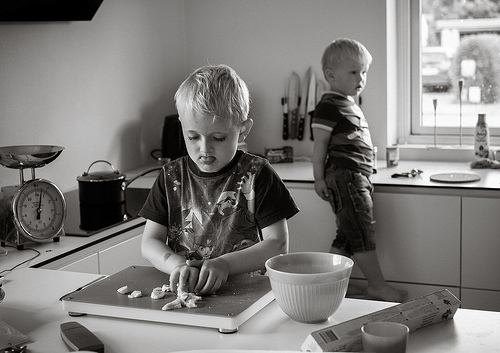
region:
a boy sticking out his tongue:
[196, 152, 221, 164]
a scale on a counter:
[1, 143, 67, 250]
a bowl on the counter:
[266, 256, 354, 322]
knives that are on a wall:
[271, 63, 335, 146]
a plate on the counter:
[424, 169, 489, 188]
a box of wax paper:
[301, 287, 474, 349]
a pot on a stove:
[75, 158, 159, 210]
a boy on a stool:
[306, 27, 414, 303]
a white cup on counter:
[356, 318, 416, 351]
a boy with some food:
[117, 234, 254, 324]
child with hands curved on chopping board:
[57, 65, 287, 330]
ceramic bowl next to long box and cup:
[266, 250, 456, 350]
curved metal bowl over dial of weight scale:
[0, 140, 65, 246]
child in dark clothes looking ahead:
[310, 32, 371, 247]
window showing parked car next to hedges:
[385, 1, 495, 146]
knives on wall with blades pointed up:
[280, 55, 317, 145]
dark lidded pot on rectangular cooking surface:
[56, 155, 153, 236]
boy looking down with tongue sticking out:
[171, 60, 251, 175]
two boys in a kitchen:
[136, 35, 377, 296]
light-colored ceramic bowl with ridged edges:
[265, 251, 355, 323]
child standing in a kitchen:
[120, 59, 302, 297]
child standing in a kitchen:
[310, 34, 408, 301]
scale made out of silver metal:
[0, 134, 76, 254]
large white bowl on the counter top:
[262, 247, 357, 329]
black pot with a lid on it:
[69, 153, 171, 210]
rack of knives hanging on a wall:
[272, 63, 327, 152]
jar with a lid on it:
[465, 111, 495, 166]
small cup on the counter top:
[355, 314, 416, 352]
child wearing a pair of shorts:
[302, 37, 414, 304]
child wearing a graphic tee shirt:
[127, 64, 294, 306]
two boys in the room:
[108, 38, 394, 247]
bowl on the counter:
[266, 250, 358, 322]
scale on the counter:
[5, 133, 76, 245]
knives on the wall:
[263, 60, 323, 147]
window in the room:
[413, 22, 496, 137]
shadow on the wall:
[99, 81, 165, 168]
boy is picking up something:
[118, 259, 232, 314]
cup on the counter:
[354, 315, 409, 350]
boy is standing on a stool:
[343, 250, 400, 301]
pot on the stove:
[81, 155, 144, 191]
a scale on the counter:
[4, 145, 71, 246]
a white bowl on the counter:
[273, 257, 355, 321]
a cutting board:
[66, 264, 266, 317]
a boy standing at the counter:
[147, 67, 297, 285]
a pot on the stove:
[80, 160, 125, 200]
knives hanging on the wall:
[276, 65, 328, 132]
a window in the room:
[419, 34, 496, 134]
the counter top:
[291, 151, 496, 188]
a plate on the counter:
[432, 171, 475, 181]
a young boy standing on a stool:
[308, 39, 418, 291]